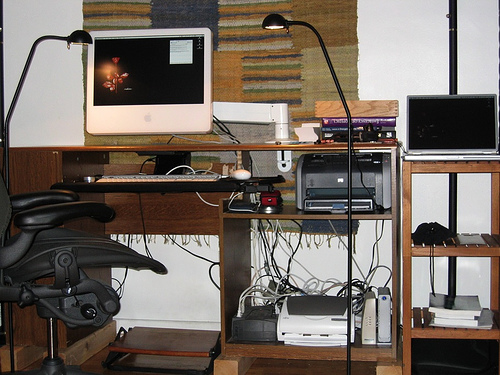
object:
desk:
[1, 139, 402, 375]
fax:
[295, 152, 392, 214]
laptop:
[403, 94, 500, 162]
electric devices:
[82, 27, 401, 348]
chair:
[0, 171, 168, 375]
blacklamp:
[261, 13, 353, 375]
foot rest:
[99, 326, 222, 374]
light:
[4, 28, 93, 194]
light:
[261, 13, 353, 117]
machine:
[276, 295, 356, 347]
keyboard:
[96, 174, 222, 182]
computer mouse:
[230, 169, 252, 180]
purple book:
[322, 117, 396, 127]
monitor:
[85, 27, 215, 136]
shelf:
[402, 159, 500, 373]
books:
[428, 292, 494, 329]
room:
[1, 0, 500, 375]